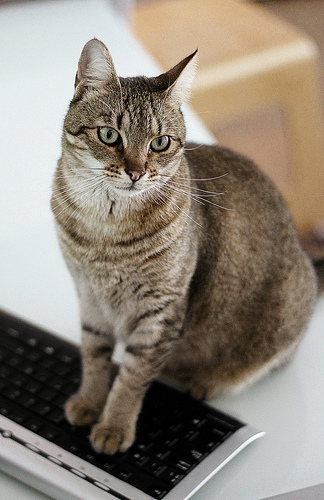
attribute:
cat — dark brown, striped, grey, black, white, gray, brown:
[45, 39, 311, 461]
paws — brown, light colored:
[59, 356, 137, 462]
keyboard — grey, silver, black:
[3, 303, 266, 499]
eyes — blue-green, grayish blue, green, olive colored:
[97, 124, 170, 155]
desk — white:
[3, 5, 312, 500]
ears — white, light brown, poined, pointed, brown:
[83, 33, 195, 97]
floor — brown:
[137, 10, 323, 245]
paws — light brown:
[171, 364, 234, 400]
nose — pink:
[128, 168, 143, 182]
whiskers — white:
[39, 158, 229, 227]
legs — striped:
[57, 256, 163, 454]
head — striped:
[58, 33, 204, 207]